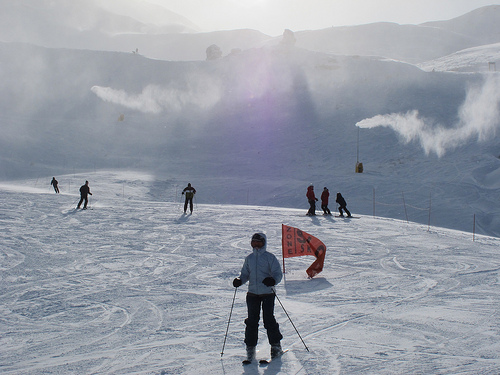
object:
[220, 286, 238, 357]
poles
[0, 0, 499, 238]
mountainous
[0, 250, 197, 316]
ski tracks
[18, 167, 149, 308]
red dress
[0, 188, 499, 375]
ground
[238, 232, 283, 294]
parka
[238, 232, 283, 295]
jacket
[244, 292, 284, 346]
pants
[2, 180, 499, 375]
snow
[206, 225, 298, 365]
cake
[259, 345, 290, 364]
ski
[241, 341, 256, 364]
ski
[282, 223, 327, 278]
flag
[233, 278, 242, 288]
gloves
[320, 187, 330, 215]
skier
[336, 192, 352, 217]
skier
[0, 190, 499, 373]
ski slope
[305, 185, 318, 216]
skier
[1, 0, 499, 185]
hill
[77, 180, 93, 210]
skier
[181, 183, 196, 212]
skier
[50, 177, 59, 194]
skier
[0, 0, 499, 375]
ski resort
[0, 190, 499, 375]
slope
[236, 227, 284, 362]
person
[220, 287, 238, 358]
ski poles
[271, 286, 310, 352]
ski poles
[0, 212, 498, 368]
run